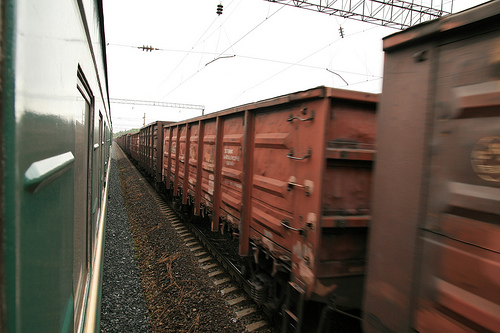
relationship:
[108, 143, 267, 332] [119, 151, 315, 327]
rails under tracks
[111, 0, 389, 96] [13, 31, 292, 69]
power lines on power line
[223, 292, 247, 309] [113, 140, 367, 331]
crosstie on tracks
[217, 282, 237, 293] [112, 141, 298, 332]
wooden crosstie on train tracks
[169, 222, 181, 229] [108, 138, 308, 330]
wooden crosstie on tracks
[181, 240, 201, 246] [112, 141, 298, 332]
crosstie on train tracks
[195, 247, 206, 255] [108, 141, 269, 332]
crosstie on rails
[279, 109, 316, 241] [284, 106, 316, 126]
ladder has rung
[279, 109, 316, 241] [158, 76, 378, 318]
ladder on car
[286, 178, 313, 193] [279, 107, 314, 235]
rung on ladder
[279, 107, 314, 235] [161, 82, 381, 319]
ladder on train car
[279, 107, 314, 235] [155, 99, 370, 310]
ladder on train car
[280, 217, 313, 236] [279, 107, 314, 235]
rung on ladder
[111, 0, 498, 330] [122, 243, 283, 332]
car on track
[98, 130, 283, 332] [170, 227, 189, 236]
gravel between tracks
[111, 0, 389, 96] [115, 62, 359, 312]
power lines passing above train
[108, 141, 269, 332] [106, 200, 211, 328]
rails on ground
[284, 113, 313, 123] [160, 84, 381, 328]
handle on cargo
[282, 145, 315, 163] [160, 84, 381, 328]
handle on cargo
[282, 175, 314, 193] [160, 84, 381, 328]
handle on cargo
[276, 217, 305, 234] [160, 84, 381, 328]
handle on cargo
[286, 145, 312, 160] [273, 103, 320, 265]
handle on cargo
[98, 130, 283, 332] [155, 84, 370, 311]
gravel between train car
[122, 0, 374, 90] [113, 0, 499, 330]
power lines hang above train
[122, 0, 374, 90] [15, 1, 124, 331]
power lines hang above train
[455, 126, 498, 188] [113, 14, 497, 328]
logo on cargo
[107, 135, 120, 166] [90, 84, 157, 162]
white circle in building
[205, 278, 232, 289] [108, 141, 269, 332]
crosstie on rails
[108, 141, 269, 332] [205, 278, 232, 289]
rails have crosstie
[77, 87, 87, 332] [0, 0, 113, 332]
window on train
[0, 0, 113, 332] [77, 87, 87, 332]
train has window